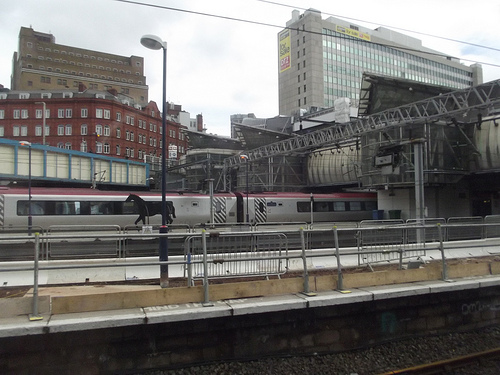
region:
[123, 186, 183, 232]
A horse in front of the train.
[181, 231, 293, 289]
A gate by the railroad tracks.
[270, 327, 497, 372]
A railroad track.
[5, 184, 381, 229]
A train stopped.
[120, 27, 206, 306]
A light next to the railroad tracks.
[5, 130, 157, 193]
A building by the train tracks.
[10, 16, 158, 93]
A building by the train tracks.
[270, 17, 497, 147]
A building behind the railroad tracks.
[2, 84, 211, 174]
A brick building behind the train tracks.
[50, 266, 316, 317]
A 2" by 6" wood board.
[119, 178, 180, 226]
a horse sign on street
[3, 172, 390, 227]
train passing by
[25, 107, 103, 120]
windows on a building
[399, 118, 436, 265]
a steel pillar pipe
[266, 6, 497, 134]
buildings in the city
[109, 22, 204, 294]
a street light of street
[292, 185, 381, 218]
windows of a train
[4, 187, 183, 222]
windows of a train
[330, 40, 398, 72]
windows on a building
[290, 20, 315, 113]
windows on a building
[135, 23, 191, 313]
a long electric poll in road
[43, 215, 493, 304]
a long bridge in road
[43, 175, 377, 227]
a train in track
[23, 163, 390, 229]
a train near road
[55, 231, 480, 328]
a long iron fence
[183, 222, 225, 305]
a small iron road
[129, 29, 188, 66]
a light on top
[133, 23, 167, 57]
a street light in top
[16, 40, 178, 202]
a big building in road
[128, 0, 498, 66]
an electric wire in top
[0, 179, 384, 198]
Top of train is red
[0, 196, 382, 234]
Side of train is silver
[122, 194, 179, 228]
Horse on side of train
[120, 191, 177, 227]
Horse is on side of train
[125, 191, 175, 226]
Black horse on side of train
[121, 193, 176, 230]
Black horse is on side of train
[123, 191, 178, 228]
Picture of horse on side of train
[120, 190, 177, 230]
Picture of horse is on side of train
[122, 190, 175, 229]
Picture of black horse on side of train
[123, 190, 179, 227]
Picture of black horse is on side of train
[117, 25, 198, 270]
light above the platform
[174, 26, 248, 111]
gray clouds in the sky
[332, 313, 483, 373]
gravel beneath the platform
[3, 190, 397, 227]
the train across the platform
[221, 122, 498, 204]
the walkway above the train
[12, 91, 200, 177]
the red building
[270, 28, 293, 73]
yellow advert on the building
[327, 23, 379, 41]
yellow banner on the building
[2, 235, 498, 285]
the platform is empty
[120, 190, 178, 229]
black horse beside the train